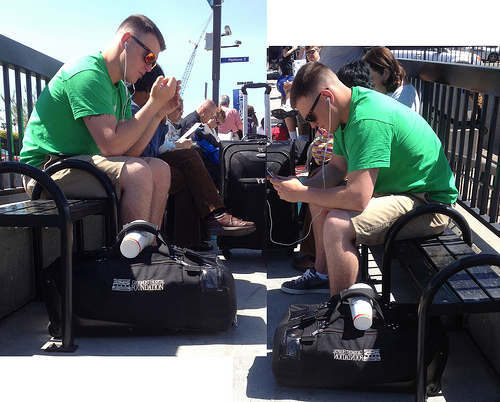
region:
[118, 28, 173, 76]
man has on sunglasses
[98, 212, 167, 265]
a white cup with red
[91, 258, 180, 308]
a black bag white letters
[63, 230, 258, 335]
a bag with black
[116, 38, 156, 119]
man has in earbuds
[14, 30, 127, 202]
man wearing green shirt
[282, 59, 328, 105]
man has a short hair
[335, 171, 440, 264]
man has on cargo shorts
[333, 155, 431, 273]
shorts are tan brown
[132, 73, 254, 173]
a group of people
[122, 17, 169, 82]
a man wearing sunglasses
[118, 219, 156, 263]
a paper cup on a bag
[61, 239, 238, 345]
a black overnight bag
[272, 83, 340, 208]
a man wearing ear phones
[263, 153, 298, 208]
a man holding a cell phone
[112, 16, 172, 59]
a man with short hair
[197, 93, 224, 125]
a man with no hair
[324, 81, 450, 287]
a man sitting on a bench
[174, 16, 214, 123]
a tall construction crane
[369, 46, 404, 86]
a woman with brown hair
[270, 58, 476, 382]
this is a man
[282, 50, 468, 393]
the man is sitting down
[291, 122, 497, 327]
man sitting on a bench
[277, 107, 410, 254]
man leaning on knees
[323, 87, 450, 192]
man wearing a green shirt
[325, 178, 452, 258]
man wearing khaki shorts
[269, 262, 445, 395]
black bag on ground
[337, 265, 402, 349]
white cup on bag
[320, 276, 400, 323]
black handle on bag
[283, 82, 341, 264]
man is wearing headphones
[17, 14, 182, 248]
Man looking at his nails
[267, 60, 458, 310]
man looking at phone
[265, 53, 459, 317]
man listening to headphones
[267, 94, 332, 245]
headphones are white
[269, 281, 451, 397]
cup in handles of bag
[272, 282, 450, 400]
bag is black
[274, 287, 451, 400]
bag has wheels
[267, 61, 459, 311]
man wearing sunglasses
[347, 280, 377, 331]
cup is white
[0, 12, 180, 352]
man sitting on bench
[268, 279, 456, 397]
Bag on the ground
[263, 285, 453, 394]
Bag is on the ground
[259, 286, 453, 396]
Black bag on the ground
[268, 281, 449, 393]
Black bag is on the ground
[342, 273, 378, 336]
Cup on a bag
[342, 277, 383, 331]
Cup is on a bag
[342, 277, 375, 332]
Cup on a black bag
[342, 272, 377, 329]
Cup is on a black bag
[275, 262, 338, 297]
Man wearing black and white shoes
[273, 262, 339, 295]
Man is wearing black and white shoes